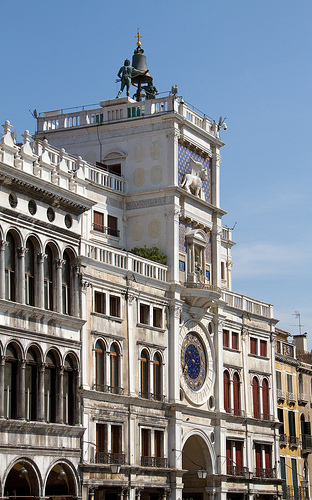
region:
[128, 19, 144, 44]
gold religious cross on top of golden ball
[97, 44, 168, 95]
statues of men with weapons surrounding large bell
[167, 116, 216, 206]
winged animal in front of gold and blue background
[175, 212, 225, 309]
round terrace under entryway flanked by columns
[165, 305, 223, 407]
gold figures in a circle with a dark blue center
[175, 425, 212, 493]
lantern hanging in front of high archway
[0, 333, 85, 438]
repeated arches and columns on building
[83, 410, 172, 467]
terraces in front of flat double doors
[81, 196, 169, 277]
wide terrace with tree in corner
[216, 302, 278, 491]
white building with windows covered in deep red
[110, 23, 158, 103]
A bell and statue atop a building.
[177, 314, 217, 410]
Circular blue ornate wall design on a building.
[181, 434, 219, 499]
Archway at the base of a building.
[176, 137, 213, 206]
Statue of a winged animal on the side of a building.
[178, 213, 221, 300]
Balcony and pillars leading to an entrance on the side of a building.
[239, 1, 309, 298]
The blue sky behind buildings.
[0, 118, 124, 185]
Railing on the top of a building.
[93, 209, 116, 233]
red closed windows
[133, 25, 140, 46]
a golden cross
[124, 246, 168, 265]
Bush on a balcony.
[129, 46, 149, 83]
a bell on top of the building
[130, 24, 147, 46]
a cross on top of the bell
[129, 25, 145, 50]
the cross is a gold color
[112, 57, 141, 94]
a statue by the bell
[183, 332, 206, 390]
a large blue clock on the building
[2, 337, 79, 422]
the windows are arched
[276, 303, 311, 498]
this building has an antenna on top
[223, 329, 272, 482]
the buildings windows have a red color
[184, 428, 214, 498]
the opening is an archway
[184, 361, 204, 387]
the clock has gold on it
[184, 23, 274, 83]
this is the sky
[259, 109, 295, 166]
the sky is blue in color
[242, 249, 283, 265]
these are the clouds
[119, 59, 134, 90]
this is a statue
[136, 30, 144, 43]
this is a cross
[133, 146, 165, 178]
this is a wall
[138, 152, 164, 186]
the wall looks old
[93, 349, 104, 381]
this is the window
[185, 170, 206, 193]
this is a horse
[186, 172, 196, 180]
the horse is white in color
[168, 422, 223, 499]
an arched opening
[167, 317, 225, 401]
a large round clock face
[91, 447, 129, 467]
railing at a balcony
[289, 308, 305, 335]
an antenna on top of a building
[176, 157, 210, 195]
a statue of a winged animal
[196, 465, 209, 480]
a light in front of a building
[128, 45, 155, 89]
a bell on top of a building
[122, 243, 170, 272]
a green plant on a balcony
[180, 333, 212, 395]
gold numbers on a clock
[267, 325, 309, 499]
a yellow building